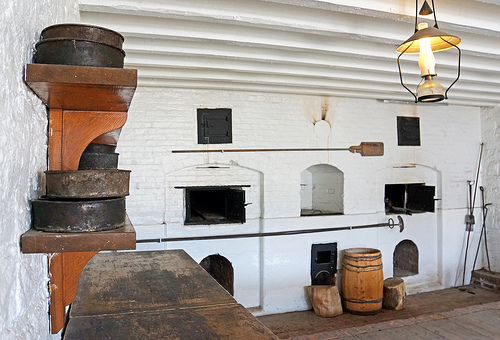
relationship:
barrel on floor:
[341, 247, 384, 314] [251, 281, 499, 339]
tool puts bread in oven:
[171, 142, 385, 157] [187, 187, 244, 225]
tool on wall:
[171, 142, 385, 157] [114, 89, 500, 319]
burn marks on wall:
[309, 95, 331, 124] [114, 89, 500, 319]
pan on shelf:
[46, 168, 132, 199] [20, 208, 138, 335]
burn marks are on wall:
[309, 95, 331, 124] [114, 89, 500, 319]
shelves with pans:
[22, 61, 138, 333] [26, 25, 132, 234]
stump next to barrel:
[383, 276, 408, 309] [341, 247, 384, 314]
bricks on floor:
[286, 299, 499, 336] [251, 281, 499, 339]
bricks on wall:
[233, 108, 311, 143] [114, 89, 500, 319]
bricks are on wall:
[233, 108, 311, 143] [114, 89, 500, 319]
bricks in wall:
[233, 108, 311, 143] [114, 89, 500, 319]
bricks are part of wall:
[233, 108, 311, 143] [114, 89, 500, 319]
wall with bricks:
[114, 89, 500, 319] [233, 108, 311, 143]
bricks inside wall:
[233, 108, 311, 143] [114, 89, 500, 319]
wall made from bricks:
[114, 89, 500, 319] [233, 108, 311, 143]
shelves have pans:
[22, 61, 138, 333] [26, 25, 132, 234]